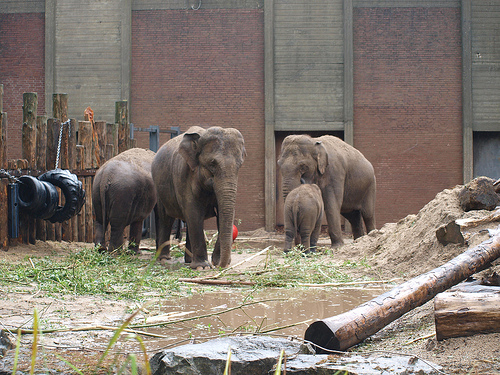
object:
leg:
[107, 213, 129, 252]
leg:
[181, 203, 215, 261]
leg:
[128, 221, 142, 248]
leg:
[154, 203, 159, 251]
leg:
[320, 178, 345, 242]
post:
[76, 145, 85, 190]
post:
[67, 119, 77, 172]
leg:
[360, 202, 375, 235]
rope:
[0, 119, 72, 183]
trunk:
[196, 143, 249, 290]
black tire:
[11, 175, 40, 208]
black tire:
[28, 180, 59, 220]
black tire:
[37, 169, 85, 223]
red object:
[231, 224, 239, 240]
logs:
[20, 91, 36, 177]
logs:
[36, 115, 46, 179]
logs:
[17, 208, 28, 245]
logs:
[5, 159, 17, 183]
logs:
[0, 82, 8, 252]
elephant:
[91, 148, 157, 256]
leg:
[211, 203, 220, 259]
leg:
[341, 210, 365, 239]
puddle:
[6, 286, 396, 371]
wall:
[352, 8, 464, 234]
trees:
[13, 242, 393, 298]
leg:
[156, 206, 175, 254]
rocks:
[149, 335, 314, 374]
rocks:
[266, 351, 444, 375]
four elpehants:
[90, 125, 375, 271]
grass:
[194, 243, 370, 292]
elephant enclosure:
[5, 92, 194, 252]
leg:
[184, 223, 192, 260]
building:
[0, 0, 500, 253]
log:
[433, 292, 497, 341]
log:
[302, 235, 499, 354]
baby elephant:
[284, 184, 325, 254]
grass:
[0, 241, 198, 302]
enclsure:
[0, 86, 500, 372]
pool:
[0, 286, 391, 374]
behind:
[277, 134, 377, 248]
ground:
[2, 176, 499, 375]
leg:
[91, 207, 109, 245]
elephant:
[150, 126, 248, 271]